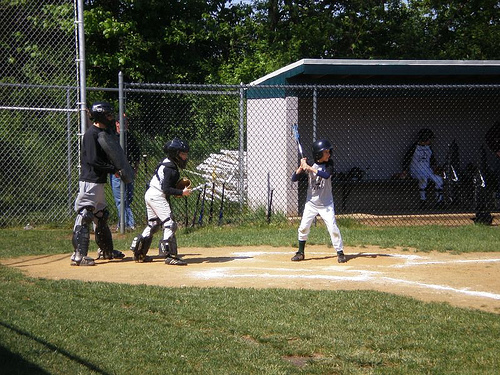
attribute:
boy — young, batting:
[292, 141, 348, 265]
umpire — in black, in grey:
[71, 101, 127, 263]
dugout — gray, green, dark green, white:
[238, 62, 496, 229]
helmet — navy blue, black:
[311, 138, 329, 161]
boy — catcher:
[128, 143, 187, 266]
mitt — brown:
[172, 177, 192, 197]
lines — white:
[180, 257, 499, 304]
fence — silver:
[3, 1, 499, 215]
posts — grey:
[234, 83, 246, 215]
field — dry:
[7, 249, 498, 368]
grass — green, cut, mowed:
[5, 273, 498, 366]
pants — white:
[295, 204, 342, 247]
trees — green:
[3, 2, 499, 78]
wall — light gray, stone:
[249, 101, 300, 219]